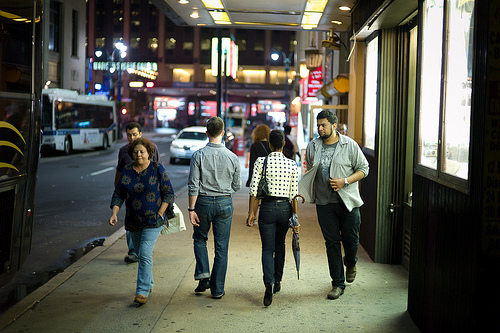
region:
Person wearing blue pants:
[115, 217, 158, 309]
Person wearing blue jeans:
[182, 190, 233, 306]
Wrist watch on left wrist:
[183, 203, 198, 214]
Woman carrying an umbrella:
[283, 187, 310, 281]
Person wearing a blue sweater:
[100, 154, 178, 239]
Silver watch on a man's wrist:
[338, 174, 352, 190]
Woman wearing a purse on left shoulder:
[246, 149, 275, 207]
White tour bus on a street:
[42, 80, 121, 152]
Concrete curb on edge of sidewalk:
[59, 234, 108, 272]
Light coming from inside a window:
[424, 26, 461, 159]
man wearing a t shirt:
[308, 97, 363, 302]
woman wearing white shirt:
[250, 117, 310, 313]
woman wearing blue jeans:
[235, 131, 301, 327]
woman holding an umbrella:
[247, 120, 308, 320]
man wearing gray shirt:
[180, 105, 246, 301]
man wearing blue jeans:
[190, 115, 250, 320]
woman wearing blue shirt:
[100, 135, 166, 317]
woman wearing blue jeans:
[105, 135, 177, 310]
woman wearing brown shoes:
[106, 137, 166, 322]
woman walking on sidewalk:
[247, 117, 319, 319]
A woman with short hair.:
[105, 135, 185, 247]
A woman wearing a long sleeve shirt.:
[109, 135, 178, 232]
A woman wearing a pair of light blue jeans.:
[104, 124, 190, 302]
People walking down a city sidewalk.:
[91, 87, 401, 320]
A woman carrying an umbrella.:
[250, 117, 310, 292]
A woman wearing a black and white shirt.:
[245, 121, 305, 221]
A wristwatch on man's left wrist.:
[182, 115, 247, 216]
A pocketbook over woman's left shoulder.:
[245, 125, 305, 230]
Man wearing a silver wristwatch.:
[305, 100, 370, 200]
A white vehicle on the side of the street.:
[170, 101, 211, 162]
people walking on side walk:
[93, 80, 395, 317]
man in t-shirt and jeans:
[301, 99, 414, 309]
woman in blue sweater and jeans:
[110, 131, 190, 311]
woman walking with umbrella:
[252, 120, 314, 325]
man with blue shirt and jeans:
[182, 104, 252, 312]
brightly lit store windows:
[415, 10, 491, 223]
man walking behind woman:
[100, 110, 180, 325]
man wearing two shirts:
[295, 99, 396, 307]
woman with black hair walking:
[245, 128, 317, 328]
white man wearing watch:
[182, 115, 253, 309]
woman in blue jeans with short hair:
[105, 135, 182, 311]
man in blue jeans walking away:
[187, 114, 240, 304]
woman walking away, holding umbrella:
[249, 127, 304, 312]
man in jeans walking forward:
[304, 108, 371, 300]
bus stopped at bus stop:
[42, 87, 118, 154]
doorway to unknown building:
[363, 6, 428, 321]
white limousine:
[169, 119, 218, 159]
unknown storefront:
[149, 92, 295, 127]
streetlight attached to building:
[296, 35, 336, 85]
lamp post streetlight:
[110, 38, 125, 143]